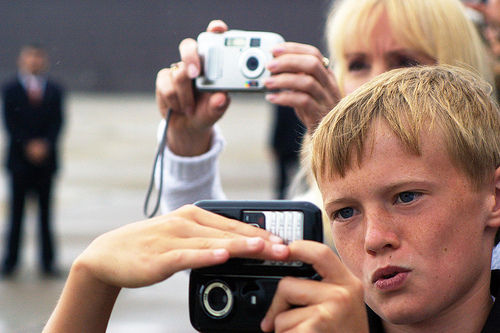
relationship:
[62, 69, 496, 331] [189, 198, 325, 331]
boy holding phone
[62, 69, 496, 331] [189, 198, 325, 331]
boy using cell phone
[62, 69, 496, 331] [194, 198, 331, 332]
person taking a picture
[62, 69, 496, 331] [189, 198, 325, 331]
boy holding cellphone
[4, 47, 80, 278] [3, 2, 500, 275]
man in background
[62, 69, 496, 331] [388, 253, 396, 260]
boy has mole